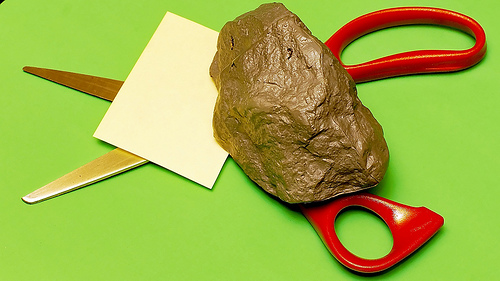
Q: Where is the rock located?
A: On top.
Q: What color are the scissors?
A: Red.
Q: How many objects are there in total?
A: Three.